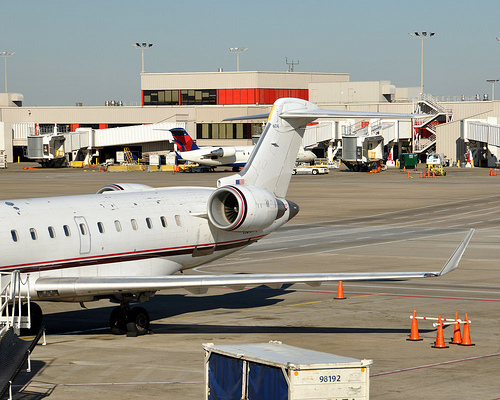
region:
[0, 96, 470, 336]
Plane on the tarmac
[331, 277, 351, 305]
Safety cone on ground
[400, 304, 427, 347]
Safety cone on ground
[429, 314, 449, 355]
Safety cone on ground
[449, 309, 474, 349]
Two safety cones on ground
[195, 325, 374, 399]
Luggage cart on tarmac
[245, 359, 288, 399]
Blue curtain on luggage cart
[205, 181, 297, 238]
Engine on the plane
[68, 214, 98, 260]
Door on the plane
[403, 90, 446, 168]
Stairs in the background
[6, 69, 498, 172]
A building for the passengers in the back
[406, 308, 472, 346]
Some orange cones on the ground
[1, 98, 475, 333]
An airplane on the tarmac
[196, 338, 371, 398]
A container to hold the luggage in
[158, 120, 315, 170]
Another plane sitting around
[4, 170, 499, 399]
the ground the planes are sitting on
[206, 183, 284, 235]
the engine on the plane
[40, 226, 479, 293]
a wing on the plane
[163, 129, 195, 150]
the colorful tail of the other plane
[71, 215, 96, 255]
a door on the plane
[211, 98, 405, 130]
tail fin of plane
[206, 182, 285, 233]
white jet engine on back of plane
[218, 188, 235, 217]
silver turbine inside engine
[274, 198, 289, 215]
grey tip on back of engine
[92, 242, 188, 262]
black and red line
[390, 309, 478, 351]
orange cone on tarmac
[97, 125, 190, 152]
white walkway for plaes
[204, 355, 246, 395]
blue curtain on vehicle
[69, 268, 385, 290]
long white wing of plane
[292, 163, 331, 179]
vehicle on tarmac parked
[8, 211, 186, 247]
Windows on side of the plane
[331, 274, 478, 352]
Five traffic cones are orange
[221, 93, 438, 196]
A tail of a plane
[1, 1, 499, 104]
A clear and blue sky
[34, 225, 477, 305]
Wing of a plane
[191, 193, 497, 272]
White lines on the tarmac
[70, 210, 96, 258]
A door on the plane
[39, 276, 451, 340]
Plane's shadow on the tarmac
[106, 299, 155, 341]
Two black round wheels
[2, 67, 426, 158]
A white building in the background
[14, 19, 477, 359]
an airfield at the airport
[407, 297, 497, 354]
orange cones on the ground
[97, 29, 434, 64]
lights on top of the airport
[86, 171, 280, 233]
two engines on the airplane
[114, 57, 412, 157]
the main terminal at the airport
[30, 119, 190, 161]
a sky bridge in the background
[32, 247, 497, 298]
the wing of the air plane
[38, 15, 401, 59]
a clear sky above the airport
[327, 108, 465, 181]
equipment and gear at the airport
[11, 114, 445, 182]
structures for supporting the airport